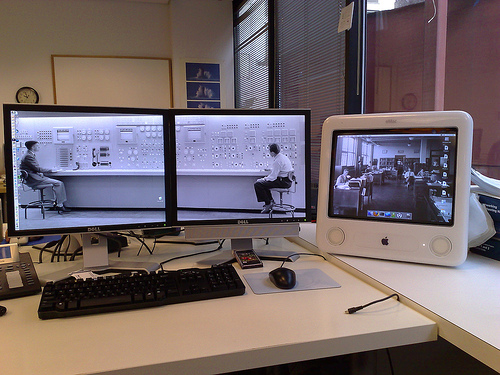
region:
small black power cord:
[320, 286, 405, 318]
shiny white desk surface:
[127, 310, 292, 342]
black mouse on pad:
[253, 251, 303, 296]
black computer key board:
[41, 256, 260, 321]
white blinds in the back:
[276, 77, 351, 96]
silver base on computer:
[213, 221, 277, 271]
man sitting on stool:
[246, 140, 297, 210]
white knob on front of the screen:
[418, 224, 442, 271]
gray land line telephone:
[1, 246, 44, 296]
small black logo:
[373, 228, 397, 249]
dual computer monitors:
[3, 105, 315, 270]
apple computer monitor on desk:
[312, 107, 477, 269]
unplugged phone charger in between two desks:
[343, 291, 401, 316]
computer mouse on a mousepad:
[266, 251, 326, 289]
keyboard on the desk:
[35, 263, 246, 322]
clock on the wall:
[13, 84, 40, 106]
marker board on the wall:
[48, 53, 174, 113]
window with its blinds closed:
[267, 0, 361, 226]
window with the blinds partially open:
[230, 0, 272, 112]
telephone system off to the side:
[0, 242, 44, 303]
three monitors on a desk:
[7, 33, 499, 321]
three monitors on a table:
[9, 57, 499, 251]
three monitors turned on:
[4, 44, 493, 332]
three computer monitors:
[16, 26, 478, 298]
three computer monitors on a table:
[4, 48, 497, 288]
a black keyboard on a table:
[26, 239, 249, 321]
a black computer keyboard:
[33, 251, 260, 323]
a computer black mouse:
[239, 234, 306, 303]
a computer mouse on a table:
[254, 244, 310, 305]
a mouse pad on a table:
[252, 251, 365, 309]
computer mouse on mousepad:
[262, 260, 300, 295]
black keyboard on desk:
[31, 258, 251, 319]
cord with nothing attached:
[343, 291, 410, 319]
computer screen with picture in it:
[171, 103, 313, 229]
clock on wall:
[13, 83, 41, 106]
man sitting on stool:
[250, 140, 299, 215]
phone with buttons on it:
[0, 243, 42, 300]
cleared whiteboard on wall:
[46, 50, 178, 112]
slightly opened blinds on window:
[233, 14, 273, 113]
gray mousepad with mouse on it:
[241, 264, 344, 295]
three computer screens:
[19, 102, 460, 244]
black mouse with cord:
[260, 247, 322, 287]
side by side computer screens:
[2, 98, 308, 240]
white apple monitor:
[307, 99, 481, 270]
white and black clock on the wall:
[7, 78, 43, 106]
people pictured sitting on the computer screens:
[16, 136, 293, 214]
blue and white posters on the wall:
[185, 57, 219, 107]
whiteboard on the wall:
[50, 48, 180, 114]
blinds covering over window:
[272, 14, 352, 157]